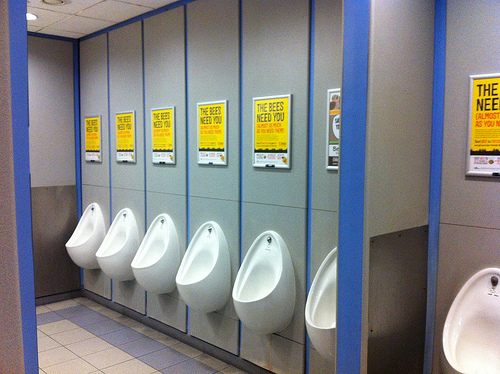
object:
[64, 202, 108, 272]
white urinal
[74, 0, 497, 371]
wall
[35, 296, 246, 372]
floor tile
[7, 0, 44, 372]
blue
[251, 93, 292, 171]
framed advertisement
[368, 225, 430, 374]
wall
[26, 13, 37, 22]
white light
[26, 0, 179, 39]
ceiling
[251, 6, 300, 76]
gray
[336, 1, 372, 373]
blue trim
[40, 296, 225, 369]
blue and grey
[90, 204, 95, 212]
metal bolt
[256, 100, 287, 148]
yellow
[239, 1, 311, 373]
panel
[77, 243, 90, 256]
white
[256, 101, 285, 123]
bees need you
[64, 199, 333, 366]
row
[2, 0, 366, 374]
archway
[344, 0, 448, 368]
wall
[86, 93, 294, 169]
five signs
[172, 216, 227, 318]
white urinal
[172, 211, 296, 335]
two urinals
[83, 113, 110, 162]
sign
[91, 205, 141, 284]
urinal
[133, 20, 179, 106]
gray and blue stripe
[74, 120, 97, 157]
yellow,white & blue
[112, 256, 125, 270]
white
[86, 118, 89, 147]
yellow